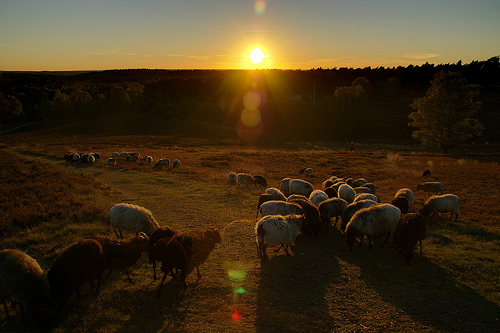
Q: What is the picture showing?
A: It is showing a field.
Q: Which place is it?
A: It is a field.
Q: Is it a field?
A: Yes, it is a field.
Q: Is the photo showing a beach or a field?
A: It is showing a field.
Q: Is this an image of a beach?
A: No, the picture is showing a field.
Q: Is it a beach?
A: No, it is a field.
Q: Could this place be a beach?
A: No, it is a field.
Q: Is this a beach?
A: No, it is a field.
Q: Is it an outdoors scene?
A: Yes, it is outdoors.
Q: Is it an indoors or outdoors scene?
A: It is outdoors.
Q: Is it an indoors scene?
A: No, it is outdoors.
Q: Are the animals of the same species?
A: Yes, all the animals are sheep.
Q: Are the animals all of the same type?
A: Yes, all the animals are sheep.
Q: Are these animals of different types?
A: No, all the animals are sheep.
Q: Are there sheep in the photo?
A: Yes, there is a sheep.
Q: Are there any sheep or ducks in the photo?
A: Yes, there is a sheep.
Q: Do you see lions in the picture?
A: No, there are no lions.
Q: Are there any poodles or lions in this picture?
A: No, there are no lions or poodles.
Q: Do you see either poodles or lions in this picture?
A: No, there are no lions or poodles.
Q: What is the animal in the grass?
A: The animal is a sheep.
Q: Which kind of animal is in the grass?
A: The animal is a sheep.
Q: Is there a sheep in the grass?
A: Yes, there is a sheep in the grass.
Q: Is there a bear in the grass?
A: No, there is a sheep in the grass.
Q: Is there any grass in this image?
A: Yes, there is grass.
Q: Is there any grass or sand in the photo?
A: Yes, there is grass.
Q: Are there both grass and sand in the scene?
A: No, there is grass but no sand.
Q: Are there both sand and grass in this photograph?
A: No, there is grass but no sand.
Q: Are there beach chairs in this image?
A: No, there are no beach chairs.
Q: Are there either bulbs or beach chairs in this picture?
A: No, there are no beach chairs or bulbs.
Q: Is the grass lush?
A: Yes, the grass is lush.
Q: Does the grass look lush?
A: Yes, the grass is lush.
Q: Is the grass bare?
A: No, the grass is lush.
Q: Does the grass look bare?
A: No, the grass is lush.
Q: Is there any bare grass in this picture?
A: No, there is grass but it is lush.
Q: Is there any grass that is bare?
A: No, there is grass but it is lush.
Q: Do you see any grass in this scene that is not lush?
A: No, there is grass but it is lush.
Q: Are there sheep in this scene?
A: Yes, there is a sheep.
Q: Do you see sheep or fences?
A: Yes, there is a sheep.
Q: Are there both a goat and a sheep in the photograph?
A: No, there is a sheep but no goats.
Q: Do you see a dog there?
A: No, there are no dogs.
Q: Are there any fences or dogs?
A: No, there are no dogs or fences.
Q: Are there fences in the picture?
A: No, there are no fences.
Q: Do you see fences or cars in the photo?
A: No, there are no fences or cars.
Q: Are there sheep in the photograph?
A: Yes, there is a sheep.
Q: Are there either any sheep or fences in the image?
A: Yes, there is a sheep.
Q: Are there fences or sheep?
A: Yes, there is a sheep.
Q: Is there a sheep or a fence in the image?
A: Yes, there is a sheep.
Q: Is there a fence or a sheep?
A: Yes, there is a sheep.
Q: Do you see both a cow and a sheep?
A: No, there is a sheep but no cows.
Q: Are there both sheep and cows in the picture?
A: No, there is a sheep but no cows.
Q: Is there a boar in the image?
A: No, there are no boars.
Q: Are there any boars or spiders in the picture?
A: No, there are no boars or spiders.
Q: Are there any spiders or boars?
A: No, there are no boars or spiders.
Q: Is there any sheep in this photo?
A: Yes, there is a sheep.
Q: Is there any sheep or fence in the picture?
A: Yes, there is a sheep.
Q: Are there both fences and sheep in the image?
A: No, there is a sheep but no fences.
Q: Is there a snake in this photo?
A: No, there are no snakes.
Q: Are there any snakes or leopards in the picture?
A: No, there are no snakes or leopards.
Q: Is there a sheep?
A: Yes, there is a sheep.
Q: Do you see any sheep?
A: Yes, there is a sheep.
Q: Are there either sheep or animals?
A: Yes, there is a sheep.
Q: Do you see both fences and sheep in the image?
A: No, there is a sheep but no fences.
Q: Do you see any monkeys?
A: No, there are no monkeys.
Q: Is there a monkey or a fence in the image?
A: No, there are no monkeys or fences.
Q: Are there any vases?
A: No, there are no vases.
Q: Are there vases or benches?
A: No, there are no vases or benches.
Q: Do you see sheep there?
A: Yes, there is a sheep.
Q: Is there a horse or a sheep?
A: Yes, there is a sheep.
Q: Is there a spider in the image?
A: No, there are no spiders.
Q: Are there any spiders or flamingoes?
A: No, there are no spiders or flamingoes.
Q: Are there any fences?
A: No, there are no fences.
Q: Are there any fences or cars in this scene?
A: No, there are no fences or cars.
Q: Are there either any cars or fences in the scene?
A: No, there are no fences or cars.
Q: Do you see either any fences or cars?
A: No, there are no fences or cars.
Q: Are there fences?
A: No, there are no fences.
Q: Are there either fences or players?
A: No, there are no fences or players.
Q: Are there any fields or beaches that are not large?
A: No, there is a field but it is large.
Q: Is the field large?
A: Yes, the field is large.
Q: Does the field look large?
A: Yes, the field is large.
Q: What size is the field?
A: The field is large.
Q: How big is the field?
A: The field is large.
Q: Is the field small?
A: No, the field is large.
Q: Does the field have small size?
A: No, the field is large.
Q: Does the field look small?
A: No, the field is large.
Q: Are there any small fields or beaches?
A: No, there is a field but it is large.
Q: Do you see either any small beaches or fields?
A: No, there is a field but it is large.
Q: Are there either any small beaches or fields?
A: No, there is a field but it is large.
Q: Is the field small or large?
A: The field is large.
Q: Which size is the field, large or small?
A: The field is large.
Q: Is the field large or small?
A: The field is large.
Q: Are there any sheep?
A: Yes, there is a sheep.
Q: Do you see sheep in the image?
A: Yes, there is a sheep.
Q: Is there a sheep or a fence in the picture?
A: Yes, there is a sheep.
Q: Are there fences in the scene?
A: No, there are no fences.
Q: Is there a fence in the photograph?
A: No, there are no fences.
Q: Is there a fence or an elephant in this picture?
A: No, there are no fences or elephants.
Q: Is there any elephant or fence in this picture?
A: No, there are no fences or elephants.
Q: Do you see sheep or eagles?
A: Yes, there is a sheep.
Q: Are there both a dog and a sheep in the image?
A: No, there is a sheep but no dogs.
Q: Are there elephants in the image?
A: No, there are no elephants.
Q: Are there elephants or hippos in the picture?
A: No, there are no elephants or hippos.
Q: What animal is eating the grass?
A: The sheep is eating the grass.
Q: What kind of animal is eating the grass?
A: The animal is a sheep.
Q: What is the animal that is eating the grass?
A: The animal is a sheep.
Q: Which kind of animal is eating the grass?
A: The animal is a sheep.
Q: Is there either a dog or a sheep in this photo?
A: Yes, there is a sheep.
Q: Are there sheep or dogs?
A: Yes, there is a sheep.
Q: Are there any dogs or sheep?
A: Yes, there is a sheep.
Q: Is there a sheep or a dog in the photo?
A: Yes, there is a sheep.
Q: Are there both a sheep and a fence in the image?
A: No, there is a sheep but no fences.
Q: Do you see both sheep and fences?
A: No, there is a sheep but no fences.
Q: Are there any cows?
A: No, there are no cows.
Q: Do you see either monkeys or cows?
A: No, there are no cows or monkeys.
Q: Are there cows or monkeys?
A: No, there are no cows or monkeys.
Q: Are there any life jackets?
A: No, there are no life jackets.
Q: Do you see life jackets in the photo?
A: No, there are no life jackets.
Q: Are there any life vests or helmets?
A: No, there are no life vests or helmets.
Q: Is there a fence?
A: No, there are no fences.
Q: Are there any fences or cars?
A: No, there are no fences or cars.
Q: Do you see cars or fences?
A: No, there are no fences or cars.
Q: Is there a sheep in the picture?
A: Yes, there is a sheep.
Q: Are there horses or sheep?
A: Yes, there is a sheep.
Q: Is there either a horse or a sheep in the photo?
A: Yes, there is a sheep.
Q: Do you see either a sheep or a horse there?
A: Yes, there is a sheep.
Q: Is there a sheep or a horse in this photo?
A: Yes, there is a sheep.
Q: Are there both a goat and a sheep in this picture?
A: No, there is a sheep but no goats.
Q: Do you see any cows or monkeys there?
A: No, there are no cows or monkeys.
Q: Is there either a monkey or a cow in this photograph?
A: No, there are no cows or monkeys.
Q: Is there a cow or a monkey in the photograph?
A: No, there are no cows or monkeys.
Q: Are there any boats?
A: No, there are no boats.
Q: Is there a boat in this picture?
A: No, there are no boats.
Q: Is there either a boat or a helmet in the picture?
A: No, there are no boats or helmets.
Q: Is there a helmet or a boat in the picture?
A: No, there are no boats or helmets.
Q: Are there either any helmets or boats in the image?
A: No, there are no boats or helmets.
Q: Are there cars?
A: No, there are no cars.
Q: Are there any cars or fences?
A: No, there are no cars or fences.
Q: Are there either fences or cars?
A: No, there are no cars or fences.